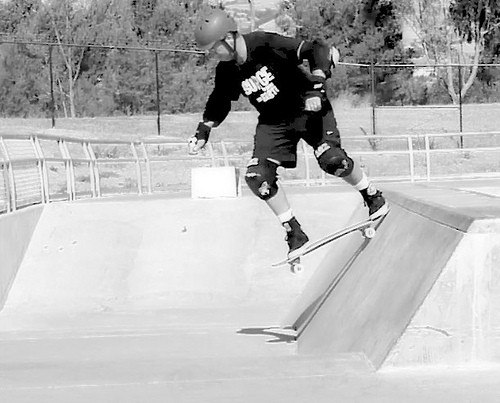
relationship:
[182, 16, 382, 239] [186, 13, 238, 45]
man wearing helmet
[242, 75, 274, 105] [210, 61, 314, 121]
lettering on shirt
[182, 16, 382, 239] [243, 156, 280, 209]
man wearing gear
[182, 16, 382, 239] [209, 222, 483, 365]
man riding on ramp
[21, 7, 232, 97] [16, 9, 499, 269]
trees behind skate park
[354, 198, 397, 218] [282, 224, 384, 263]
feet on top of skateboard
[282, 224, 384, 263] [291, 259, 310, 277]
skateboard has wheel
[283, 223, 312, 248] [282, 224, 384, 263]
shoes on skateboard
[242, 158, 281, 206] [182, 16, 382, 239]
knee pads on man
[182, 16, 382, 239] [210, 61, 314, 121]
man wearing shirt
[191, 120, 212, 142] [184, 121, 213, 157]
glove on hand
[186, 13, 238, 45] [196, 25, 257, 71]
helmet on head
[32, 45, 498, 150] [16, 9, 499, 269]
fence behind skate park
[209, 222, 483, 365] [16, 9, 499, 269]
ramp in skate park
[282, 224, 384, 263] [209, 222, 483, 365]
skateboard on ramp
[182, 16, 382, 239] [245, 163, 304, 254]
man has leg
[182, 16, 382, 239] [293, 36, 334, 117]
man has arm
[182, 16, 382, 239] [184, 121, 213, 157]
man has hand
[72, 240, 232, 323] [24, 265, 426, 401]
shadow on ground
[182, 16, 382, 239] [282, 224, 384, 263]
man on skateboard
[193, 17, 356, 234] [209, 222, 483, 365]
skateboarder on top of ramp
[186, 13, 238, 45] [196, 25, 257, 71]
helmet on top of head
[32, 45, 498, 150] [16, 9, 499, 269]
fence around skate park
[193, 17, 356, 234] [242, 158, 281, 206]
skateboarder wearing knee pads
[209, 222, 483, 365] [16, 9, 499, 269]
ramp inside skate park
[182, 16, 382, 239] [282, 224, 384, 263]
man riding skateboard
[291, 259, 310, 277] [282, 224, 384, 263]
wheel on bottom of skateboard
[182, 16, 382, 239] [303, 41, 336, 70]
man wearing elbow pad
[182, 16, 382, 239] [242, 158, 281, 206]
man wearing knee pads